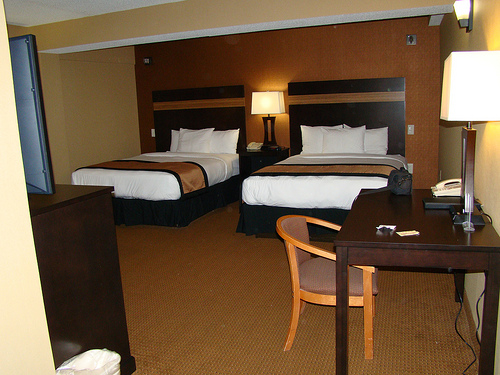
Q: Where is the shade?
A: On lamp.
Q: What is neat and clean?
A: Room.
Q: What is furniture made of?
A: Wood.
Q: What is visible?
A: Table.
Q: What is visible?
A: Table.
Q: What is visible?
A: Table.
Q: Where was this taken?
A: A hotel room.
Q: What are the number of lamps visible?
A: Two.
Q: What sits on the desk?
A: A telephone.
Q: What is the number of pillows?
A: Six.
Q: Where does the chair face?
A: The dark wood desk.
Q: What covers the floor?
A: Orange brownish carpet.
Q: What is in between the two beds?
A: Nightstand.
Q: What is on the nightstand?
A: Lamp.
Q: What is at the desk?
A: Chair.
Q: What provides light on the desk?
A: Lamp.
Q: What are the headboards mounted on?
A: Wall.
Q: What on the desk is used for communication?
A: Phone.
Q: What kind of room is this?
A: Hotel room.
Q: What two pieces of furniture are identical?
A: Beds.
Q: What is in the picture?
A: A bedroom.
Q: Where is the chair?
A: Near the front by the stand.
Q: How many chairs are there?
A: One.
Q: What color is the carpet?
A: Brown.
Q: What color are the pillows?
A: White.